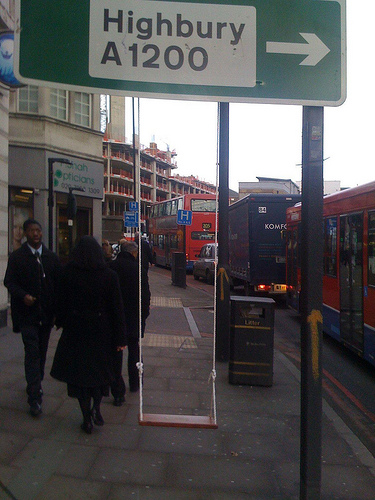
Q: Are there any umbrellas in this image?
A: No, there are no umbrellas.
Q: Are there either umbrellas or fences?
A: No, there are no umbrellas or fences.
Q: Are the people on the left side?
A: Yes, the people are on the left of the image.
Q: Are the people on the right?
A: No, the people are on the left of the image.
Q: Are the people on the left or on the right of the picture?
A: The people are on the left of the image.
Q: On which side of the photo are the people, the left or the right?
A: The people are on the left of the image.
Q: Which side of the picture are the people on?
A: The people are on the left of the image.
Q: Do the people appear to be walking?
A: Yes, the people are walking.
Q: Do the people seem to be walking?
A: Yes, the people are walking.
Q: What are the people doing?
A: The people are walking.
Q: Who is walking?
A: The people are walking.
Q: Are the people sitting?
A: No, the people are walking.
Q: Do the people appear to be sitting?
A: No, the people are walking.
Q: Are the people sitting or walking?
A: The people are walking.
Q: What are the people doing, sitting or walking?
A: The people are walking.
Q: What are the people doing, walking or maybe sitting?
A: The people are walking.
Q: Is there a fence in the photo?
A: No, there are no fences.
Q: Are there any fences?
A: No, there are no fences.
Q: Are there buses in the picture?
A: Yes, there are buses.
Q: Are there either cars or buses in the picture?
A: Yes, there are buses.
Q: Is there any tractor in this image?
A: No, there are no tractors.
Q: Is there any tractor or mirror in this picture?
A: No, there are no tractors or mirrors.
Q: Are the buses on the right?
A: Yes, the buses are on the right of the image.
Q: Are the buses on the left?
A: No, the buses are on the right of the image.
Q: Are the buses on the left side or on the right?
A: The buses are on the right of the image.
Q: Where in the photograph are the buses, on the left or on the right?
A: The buses are on the right of the image.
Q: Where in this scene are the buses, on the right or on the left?
A: The buses are on the right of the image.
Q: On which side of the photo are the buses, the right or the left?
A: The buses are on the right of the image.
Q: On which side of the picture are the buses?
A: The buses are on the right of the image.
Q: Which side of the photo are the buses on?
A: The buses are on the right of the image.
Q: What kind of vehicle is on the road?
A: The vehicles are buses.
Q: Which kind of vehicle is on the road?
A: The vehicles are buses.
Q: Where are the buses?
A: The buses are on the road.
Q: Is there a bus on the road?
A: Yes, there are buses on the road.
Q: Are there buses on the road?
A: Yes, there are buses on the road.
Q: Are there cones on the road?
A: No, there are buses on the road.